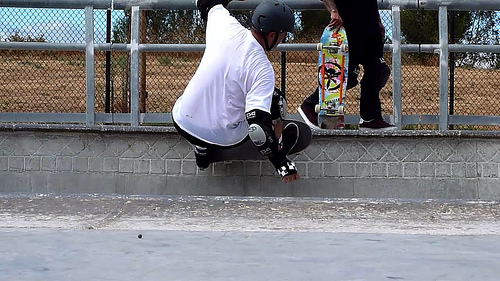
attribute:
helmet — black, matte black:
[252, 0, 295, 51]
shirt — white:
[172, 4, 275, 146]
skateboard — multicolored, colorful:
[314, 24, 349, 129]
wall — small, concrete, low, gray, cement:
[0, 122, 500, 200]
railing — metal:
[0, 0, 500, 12]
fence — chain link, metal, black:
[0, 7, 500, 131]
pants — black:
[304, 29, 384, 118]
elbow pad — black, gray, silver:
[245, 109, 279, 156]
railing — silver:
[1, 0, 500, 130]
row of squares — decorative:
[0, 156, 500, 178]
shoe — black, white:
[281, 122, 299, 156]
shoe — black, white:
[196, 156, 210, 171]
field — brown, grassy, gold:
[1, 56, 500, 130]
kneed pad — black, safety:
[359, 57, 390, 90]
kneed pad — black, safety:
[346, 64, 360, 89]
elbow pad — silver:
[196, 0, 233, 22]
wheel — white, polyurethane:
[317, 42, 324, 50]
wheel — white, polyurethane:
[340, 44, 347, 53]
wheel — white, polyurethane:
[315, 104, 322, 113]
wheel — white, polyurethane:
[337, 105, 344, 113]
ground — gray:
[1, 227, 500, 280]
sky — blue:
[0, 6, 500, 68]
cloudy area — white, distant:
[0, 21, 106, 44]